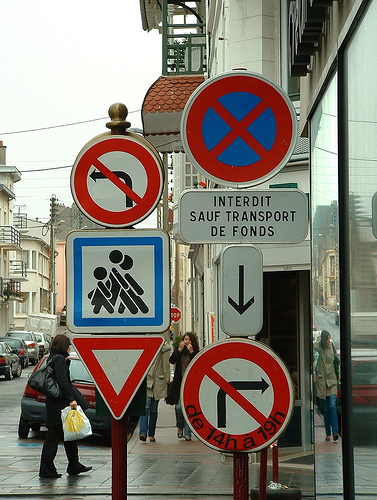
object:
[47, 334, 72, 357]
head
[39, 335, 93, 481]
person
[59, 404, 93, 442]
plastic bag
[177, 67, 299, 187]
sign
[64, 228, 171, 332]
sign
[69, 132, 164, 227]
sign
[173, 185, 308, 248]
sign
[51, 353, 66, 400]
shoulder bag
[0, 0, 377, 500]
outside scene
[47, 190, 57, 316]
telephone pole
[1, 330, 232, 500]
street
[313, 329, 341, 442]
reflection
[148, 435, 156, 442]
foot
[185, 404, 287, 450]
writing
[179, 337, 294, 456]
sign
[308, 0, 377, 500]
glass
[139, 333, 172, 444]
person